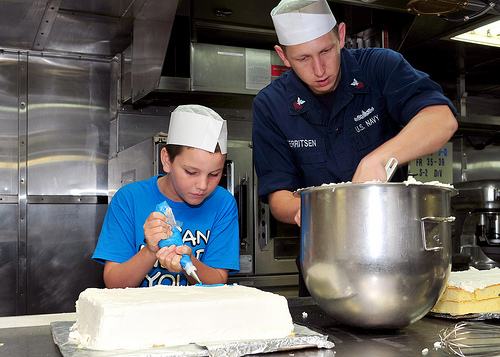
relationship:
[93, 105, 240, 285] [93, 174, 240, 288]
boy wearing a t-shirt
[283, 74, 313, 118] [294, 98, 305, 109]
collar has an emblem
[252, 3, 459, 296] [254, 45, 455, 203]
man has a uniform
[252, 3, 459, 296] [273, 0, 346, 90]
man has a head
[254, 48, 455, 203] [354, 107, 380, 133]
uniform has print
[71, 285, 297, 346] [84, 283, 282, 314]
cake has frosting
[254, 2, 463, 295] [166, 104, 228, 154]
chef has a hat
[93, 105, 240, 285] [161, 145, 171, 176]
boy has an ear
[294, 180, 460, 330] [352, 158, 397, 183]
bowl for mixing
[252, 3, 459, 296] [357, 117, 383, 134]
man in navy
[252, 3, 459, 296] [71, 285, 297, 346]
man making a cake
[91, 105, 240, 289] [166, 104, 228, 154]
boy has a hat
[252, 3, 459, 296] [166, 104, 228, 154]
man has on a hat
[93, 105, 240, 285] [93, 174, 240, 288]
boy has a t-shirt